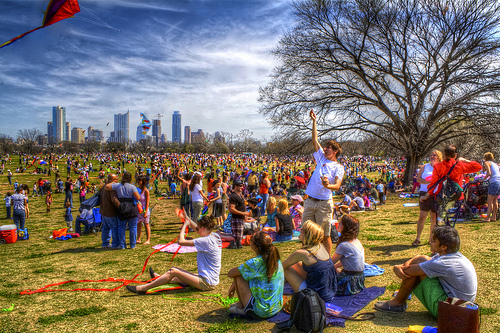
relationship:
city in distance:
[37, 101, 211, 149] [1, 101, 489, 151]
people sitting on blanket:
[280, 209, 388, 319] [332, 285, 384, 322]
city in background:
[37, 101, 211, 149] [1, 101, 489, 151]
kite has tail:
[1, 0, 86, 47] [4, 26, 43, 47]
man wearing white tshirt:
[301, 108, 345, 258] [303, 147, 345, 200]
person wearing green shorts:
[372, 222, 479, 316] [412, 270, 448, 316]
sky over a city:
[3, 4, 498, 135] [37, 101, 211, 149]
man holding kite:
[301, 108, 345, 258] [1, 0, 86, 47]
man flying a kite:
[301, 108, 345, 258] [1, 0, 86, 47]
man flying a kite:
[126, 209, 223, 289] [138, 107, 153, 137]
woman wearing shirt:
[227, 229, 291, 320] [237, 256, 286, 318]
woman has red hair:
[414, 143, 441, 241] [425, 147, 443, 162]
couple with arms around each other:
[93, 171, 146, 251] [96, 183, 121, 217]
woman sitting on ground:
[227, 229, 291, 320] [200, 306, 286, 333]